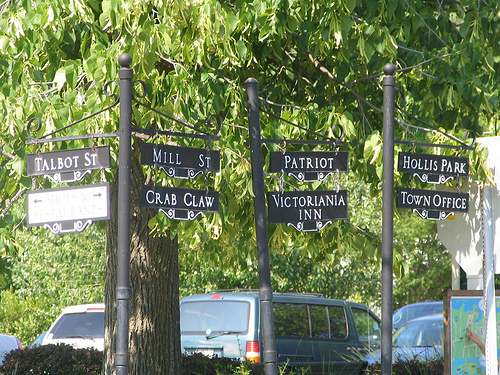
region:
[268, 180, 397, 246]
White lettering on black sign.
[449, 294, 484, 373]
a finger pointnig on a map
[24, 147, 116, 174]
a sign named Talbot St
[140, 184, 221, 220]
a sign named crab claw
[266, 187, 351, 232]
a sign named Victoriania Inn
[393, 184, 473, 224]
a signed named Town Office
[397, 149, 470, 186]
a sign named Hollis Park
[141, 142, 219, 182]
a signed named Mill St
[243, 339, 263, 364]
red white and yellow tail light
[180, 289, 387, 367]
a large blue car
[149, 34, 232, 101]
leaves on a tree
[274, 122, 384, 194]
White writing on pole.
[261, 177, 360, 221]
White writing on pole.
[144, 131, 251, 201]
White writing on sign.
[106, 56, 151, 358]
a metal pole in front of a tree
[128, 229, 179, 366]
a tree trunk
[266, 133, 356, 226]
signs hanging from a pole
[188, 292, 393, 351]
a van parked in a parking lot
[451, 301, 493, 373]
a map of the area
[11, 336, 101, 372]
shurbs by a tree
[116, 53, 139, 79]
the top of a pole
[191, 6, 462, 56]
leaves on a tree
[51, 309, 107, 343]
back glass of a car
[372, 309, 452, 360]
a parked car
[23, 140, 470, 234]
Sign posts hanging from pillars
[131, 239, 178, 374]
The trunk of a tree with some light on it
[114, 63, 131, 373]
A black iron pillar with faded paint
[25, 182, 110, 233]
A white sign post with two arrows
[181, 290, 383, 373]
A bluish suv with an pillar in forefront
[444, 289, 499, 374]
A directional map to the park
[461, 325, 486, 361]
A hand pointing to the map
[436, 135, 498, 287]
The white rear side of a sign post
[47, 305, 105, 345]
The rear window of a white car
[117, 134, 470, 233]
Four sign post mounted on three iron pillars